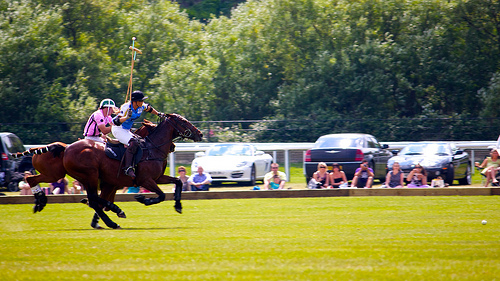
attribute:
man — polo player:
[84, 96, 120, 146]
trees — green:
[251, 2, 429, 128]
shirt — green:
[485, 156, 498, 171]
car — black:
[383, 140, 465, 177]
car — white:
[190, 143, 273, 185]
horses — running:
[81, 114, 205, 232]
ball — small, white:
[480, 217, 488, 224]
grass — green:
[0, 200, 498, 279]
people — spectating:
[26, 84, 244, 247]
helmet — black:
[128, 87, 149, 101]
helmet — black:
[98, 98, 118, 108]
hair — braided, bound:
[9, 125, 70, 176]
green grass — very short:
[0, 193, 498, 279]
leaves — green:
[1, 0, 498, 144]